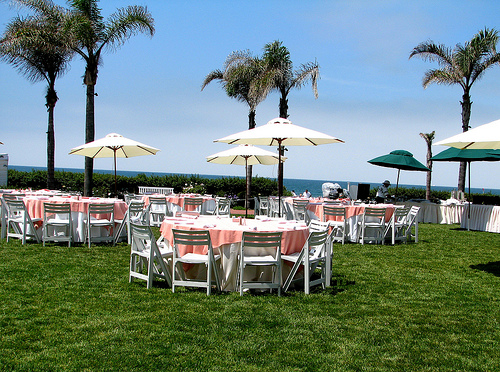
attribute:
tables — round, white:
[13, 178, 407, 283]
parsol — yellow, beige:
[194, 108, 343, 180]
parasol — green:
[359, 118, 443, 192]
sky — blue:
[1, 3, 496, 186]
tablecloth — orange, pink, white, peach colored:
[151, 205, 310, 265]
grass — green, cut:
[6, 246, 485, 372]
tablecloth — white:
[389, 174, 499, 229]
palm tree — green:
[208, 41, 285, 97]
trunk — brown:
[31, 68, 72, 187]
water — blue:
[15, 151, 438, 208]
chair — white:
[162, 209, 248, 300]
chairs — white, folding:
[111, 213, 232, 294]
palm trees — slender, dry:
[3, 2, 154, 186]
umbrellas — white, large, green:
[217, 114, 376, 198]